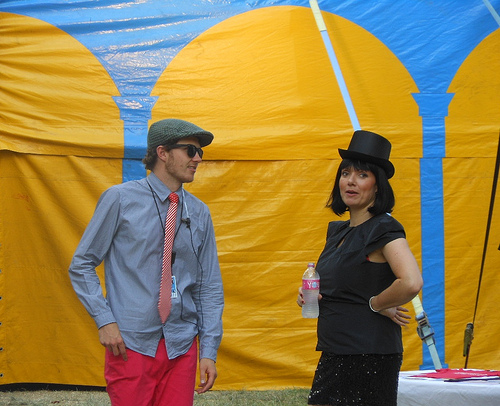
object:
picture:
[2, 1, 495, 403]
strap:
[465, 140, 500, 368]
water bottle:
[302, 262, 321, 318]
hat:
[147, 118, 213, 149]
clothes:
[306, 212, 405, 404]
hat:
[338, 129, 396, 180]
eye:
[358, 172, 368, 178]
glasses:
[167, 144, 203, 158]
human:
[309, 130, 424, 406]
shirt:
[314, 211, 405, 355]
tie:
[158, 193, 179, 323]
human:
[69, 118, 224, 403]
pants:
[104, 337, 196, 405]